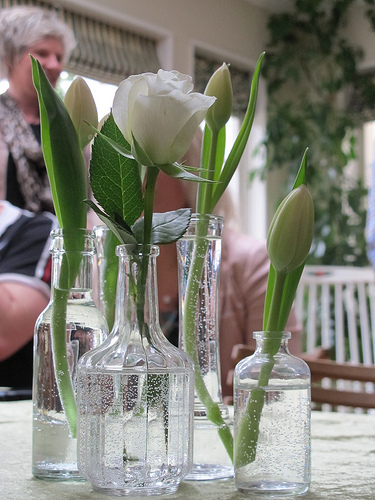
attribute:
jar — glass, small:
[231, 330, 311, 498]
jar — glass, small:
[171, 213, 233, 483]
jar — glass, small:
[75, 242, 192, 497]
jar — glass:
[31, 229, 108, 482]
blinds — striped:
[83, 30, 152, 68]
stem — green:
[88, 68, 216, 335]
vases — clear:
[179, 245, 216, 373]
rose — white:
[83, 67, 224, 187]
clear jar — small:
[217, 354, 313, 487]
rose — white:
[78, 69, 223, 335]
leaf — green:
[89, 111, 147, 223]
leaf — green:
[88, 108, 143, 228]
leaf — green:
[130, 207, 190, 242]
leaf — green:
[28, 54, 88, 290]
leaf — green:
[212, 52, 265, 207]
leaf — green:
[262, 147, 308, 358]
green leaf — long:
[61, 56, 226, 252]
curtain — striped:
[82, 18, 131, 82]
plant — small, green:
[254, 148, 337, 289]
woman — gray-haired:
[0, 4, 117, 227]